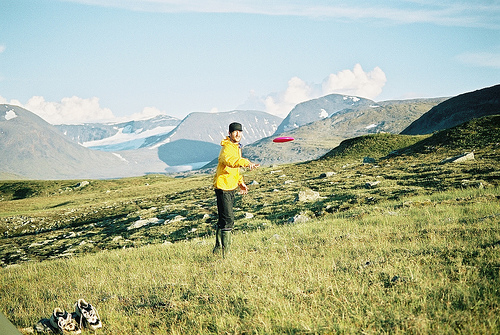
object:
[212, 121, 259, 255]
man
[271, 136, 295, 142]
frisbee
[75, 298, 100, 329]
shoe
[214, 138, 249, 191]
jacket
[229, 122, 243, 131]
hat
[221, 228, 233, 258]
boot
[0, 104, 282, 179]
mountain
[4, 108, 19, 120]
snow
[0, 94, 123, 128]
cloud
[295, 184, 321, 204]
rock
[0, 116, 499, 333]
field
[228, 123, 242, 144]
head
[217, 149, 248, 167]
arm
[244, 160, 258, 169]
hand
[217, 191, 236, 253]
leg